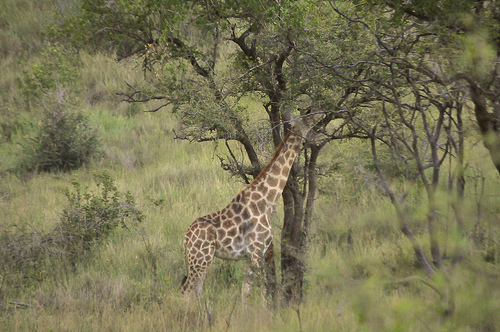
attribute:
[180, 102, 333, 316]
giraffe — eating, standing, alone, feeding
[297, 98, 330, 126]
head — hidden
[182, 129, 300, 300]
spots — brown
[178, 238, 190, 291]
tail — black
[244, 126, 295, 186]
hair — mane, brown, black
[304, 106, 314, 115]
eye — black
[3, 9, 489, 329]
grass — tall, brown, dried, dry, green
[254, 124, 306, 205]
neck — long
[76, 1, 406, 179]
branches — many, lots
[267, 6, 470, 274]
tree — leafless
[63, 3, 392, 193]
leaves — green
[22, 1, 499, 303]
bush — small, green